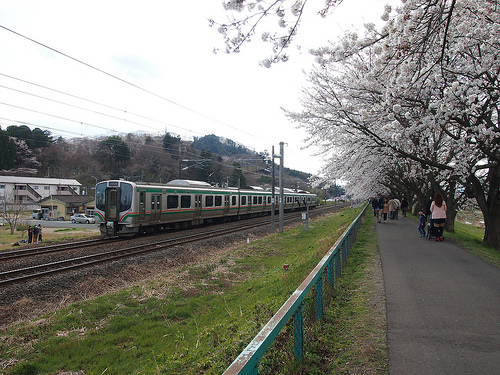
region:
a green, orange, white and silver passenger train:
[93, 178, 319, 236]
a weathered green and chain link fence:
[218, 200, 375, 373]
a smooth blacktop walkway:
[380, 241, 497, 372]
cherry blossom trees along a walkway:
[283, 33, 498, 245]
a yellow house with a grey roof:
[39, 195, 86, 221]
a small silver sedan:
[68, 213, 95, 226]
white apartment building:
[2, 176, 82, 206]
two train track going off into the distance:
[2, 201, 352, 283]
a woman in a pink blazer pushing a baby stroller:
[430, 191, 447, 239]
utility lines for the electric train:
[0, 35, 310, 185]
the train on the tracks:
[92, 178, 317, 234]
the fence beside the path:
[218, 195, 376, 374]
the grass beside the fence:
[27, 200, 353, 372]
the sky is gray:
[98, 17, 188, 57]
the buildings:
[1, 175, 91, 212]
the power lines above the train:
[7, 82, 289, 175]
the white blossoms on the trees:
[281, 8, 488, 196]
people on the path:
[377, 198, 447, 237]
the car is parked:
[51, 208, 91, 227]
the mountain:
[7, 118, 269, 162]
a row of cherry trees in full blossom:
[204, 0, 499, 249]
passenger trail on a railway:
[93, 179, 320, 239]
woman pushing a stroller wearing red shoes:
[428, 190, 447, 241]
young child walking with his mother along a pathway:
[416, 209, 426, 236]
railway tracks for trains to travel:
[1, 200, 352, 286]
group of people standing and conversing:
[26, 222, 43, 245]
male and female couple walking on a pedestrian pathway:
[372, 190, 390, 221]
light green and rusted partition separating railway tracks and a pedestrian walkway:
[221, 198, 371, 373]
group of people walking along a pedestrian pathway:
[370, 189, 410, 222]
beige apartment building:
[2, 177, 83, 210]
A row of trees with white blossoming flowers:
[278, 2, 498, 253]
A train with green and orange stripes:
[93, 178, 319, 240]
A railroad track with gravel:
[0, 199, 351, 286]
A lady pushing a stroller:
[422, 192, 448, 242]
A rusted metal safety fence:
[221, 198, 371, 374]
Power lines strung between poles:
[0, 22, 275, 187]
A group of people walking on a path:
[369, 194, 409, 226]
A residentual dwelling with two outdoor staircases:
[0, 174, 83, 213]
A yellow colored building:
[33, 192, 98, 223]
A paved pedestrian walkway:
[371, 210, 498, 373]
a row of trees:
[311, 3, 491, 250]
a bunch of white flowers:
[299, 45, 486, 196]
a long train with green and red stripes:
[92, 172, 320, 227]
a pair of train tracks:
[1, 234, 117, 285]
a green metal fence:
[271, 210, 359, 368]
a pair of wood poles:
[267, 137, 287, 237]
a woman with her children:
[416, 190, 453, 243]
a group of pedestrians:
[370, 183, 412, 221]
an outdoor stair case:
[13, 182, 46, 202]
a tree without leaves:
[0, 188, 34, 234]